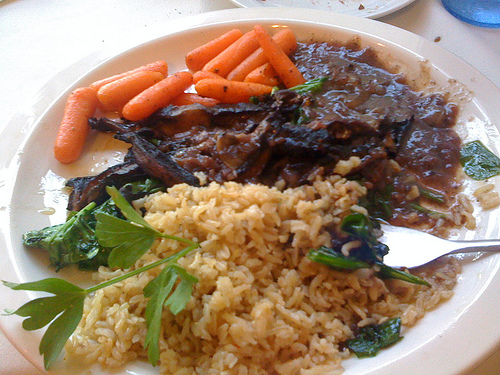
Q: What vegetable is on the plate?
A: Carrots.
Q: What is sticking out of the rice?
A: Parsley.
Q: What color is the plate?
A: White.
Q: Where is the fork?
A: In the rice.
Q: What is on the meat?
A: Sauce.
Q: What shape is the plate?
A: Round.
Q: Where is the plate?
A: On the table.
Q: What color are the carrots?
A: Orange.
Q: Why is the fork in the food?
A: To be used to eat the food.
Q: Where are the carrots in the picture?
A: At the top of the picture.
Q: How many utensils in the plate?
A: One.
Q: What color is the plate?
A: White.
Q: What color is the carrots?
A: Orange.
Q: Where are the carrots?
A: On the plate.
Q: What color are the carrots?
A: Orange.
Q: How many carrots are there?
A: 12.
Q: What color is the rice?
A: Brown.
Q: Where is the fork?
A: On the edge of the plate.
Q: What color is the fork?
A: Silver.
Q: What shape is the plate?
A: Round.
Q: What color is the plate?
A: White.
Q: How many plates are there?
A: 2.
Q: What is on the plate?
A: Food.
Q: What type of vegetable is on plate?
A: Carrots.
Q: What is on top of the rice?
A: Parsley.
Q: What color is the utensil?
A: Silver.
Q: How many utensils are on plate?
A: One.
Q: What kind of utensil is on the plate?
A: Fork.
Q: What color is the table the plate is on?
A: White.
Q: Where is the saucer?
A: Behind the plate.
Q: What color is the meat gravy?
A: Brown.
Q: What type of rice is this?
A: Brown rice.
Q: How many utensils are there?
A: One.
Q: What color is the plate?
A: White.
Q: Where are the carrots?
A: Next to the meat.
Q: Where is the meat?
A: Under the gravy.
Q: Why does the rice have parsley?
A: For decoration.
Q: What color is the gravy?
A: Brown.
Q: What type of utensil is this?
A: Folk.